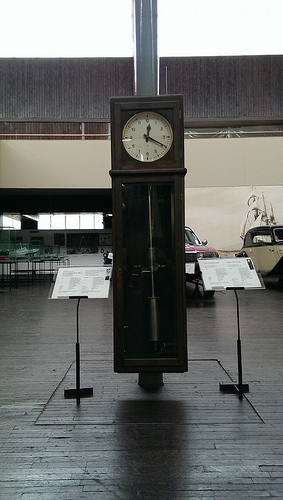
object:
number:
[145, 116, 150, 123]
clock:
[108, 88, 189, 372]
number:
[154, 120, 157, 126]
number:
[160, 126, 164, 131]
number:
[162, 134, 166, 140]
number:
[160, 143, 163, 148]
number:
[137, 121, 141, 126]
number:
[131, 126, 135, 132]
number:
[129, 135, 133, 140]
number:
[131, 143, 135, 149]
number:
[138, 148, 141, 155]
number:
[145, 151, 149, 157]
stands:
[196, 248, 263, 400]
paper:
[197, 257, 262, 290]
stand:
[53, 259, 108, 400]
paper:
[51, 266, 112, 298]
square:
[34, 355, 264, 427]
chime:
[143, 181, 162, 348]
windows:
[94, 211, 104, 230]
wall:
[14, 60, 282, 254]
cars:
[235, 221, 283, 286]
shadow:
[102, 392, 199, 499]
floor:
[0, 272, 282, 499]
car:
[183, 225, 220, 297]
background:
[3, 57, 281, 300]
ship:
[239, 190, 277, 239]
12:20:
[122, 111, 173, 162]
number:
[154, 149, 158, 154]